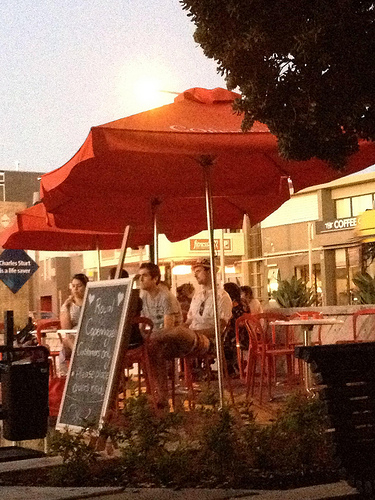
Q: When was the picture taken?
A: Daytime.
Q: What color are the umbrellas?
A: Red.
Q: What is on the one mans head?
A: A hat.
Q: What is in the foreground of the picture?
A: A bench.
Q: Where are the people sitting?
A: In chairs.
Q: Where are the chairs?
A: Next to the table.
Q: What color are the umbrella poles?
A: Silver.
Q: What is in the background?
A: Buildings.